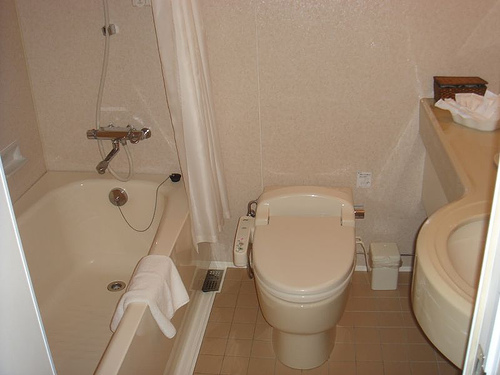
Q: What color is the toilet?
A: White.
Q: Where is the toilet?
A: In the bathroom.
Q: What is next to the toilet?
A: The tub.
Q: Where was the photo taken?
A: Bathroom.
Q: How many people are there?
A: None.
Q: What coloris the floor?
A: Tan.